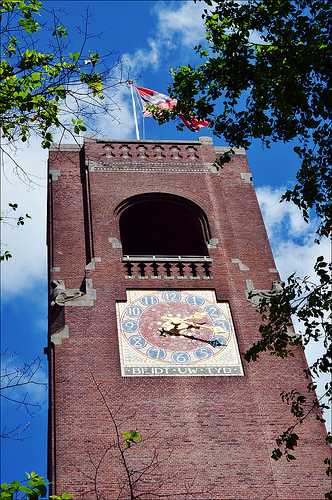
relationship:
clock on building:
[117, 280, 242, 396] [130, 149, 228, 291]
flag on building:
[117, 67, 189, 146] [130, 149, 228, 291]